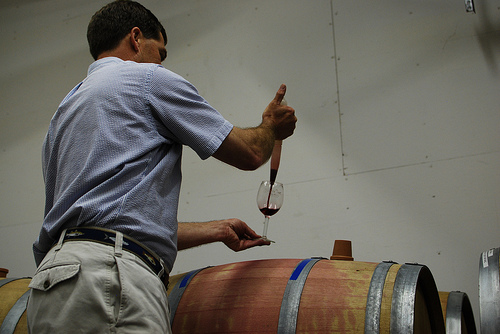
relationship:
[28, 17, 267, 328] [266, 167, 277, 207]
man getting sample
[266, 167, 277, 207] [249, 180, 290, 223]
sample of wine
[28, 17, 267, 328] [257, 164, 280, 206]
man getting sample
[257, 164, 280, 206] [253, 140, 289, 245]
sample of red wine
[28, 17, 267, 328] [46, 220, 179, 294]
man wearing belt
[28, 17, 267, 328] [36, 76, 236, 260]
man wearing shirt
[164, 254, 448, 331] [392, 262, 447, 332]
barrel has metal rim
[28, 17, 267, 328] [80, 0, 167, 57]
man has hair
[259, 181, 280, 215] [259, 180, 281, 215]
wine with wine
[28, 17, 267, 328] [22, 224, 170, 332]
man wearing pants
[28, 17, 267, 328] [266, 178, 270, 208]
man putting wine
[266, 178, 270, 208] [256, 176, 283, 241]
wine in glass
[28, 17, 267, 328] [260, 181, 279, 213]
man pouring wine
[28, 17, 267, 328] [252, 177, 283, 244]
man pouring wine in glass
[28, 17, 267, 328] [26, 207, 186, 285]
man wearing belt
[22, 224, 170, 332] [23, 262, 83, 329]
pants has back pocket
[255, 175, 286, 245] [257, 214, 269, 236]
glass has stem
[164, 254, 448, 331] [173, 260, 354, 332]
barrel has red stain